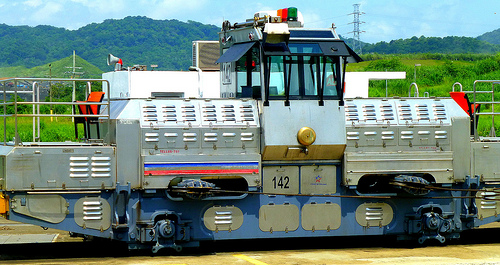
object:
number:
[271, 175, 290, 189]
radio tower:
[345, 2, 367, 55]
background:
[0, 0, 500, 72]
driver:
[212, 12, 366, 108]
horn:
[106, 52, 123, 71]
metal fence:
[0, 77, 111, 144]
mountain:
[0, 12, 222, 71]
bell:
[296, 126, 317, 146]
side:
[137, 119, 472, 189]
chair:
[449, 91, 481, 128]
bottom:
[4, 186, 500, 255]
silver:
[0, 96, 500, 190]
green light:
[286, 6, 298, 21]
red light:
[281, 8, 288, 23]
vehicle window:
[262, 165, 301, 195]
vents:
[214, 220, 233, 225]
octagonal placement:
[203, 206, 245, 231]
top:
[213, 6, 367, 71]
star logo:
[315, 175, 323, 183]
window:
[234, 42, 263, 99]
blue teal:
[214, 41, 258, 63]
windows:
[288, 43, 325, 54]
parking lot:
[1, 74, 49, 103]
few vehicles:
[1, 80, 32, 91]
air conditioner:
[191, 40, 221, 71]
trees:
[475, 33, 485, 52]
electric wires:
[302, 13, 354, 25]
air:
[303, 0, 500, 52]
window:
[266, 55, 340, 100]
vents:
[364, 131, 378, 136]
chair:
[72, 91, 106, 140]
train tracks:
[89, 232, 467, 258]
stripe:
[143, 169, 259, 176]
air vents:
[142, 99, 260, 150]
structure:
[0, 79, 500, 255]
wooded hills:
[0, 12, 496, 75]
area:
[0, 0, 500, 265]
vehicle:
[0, 6, 500, 254]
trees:
[389, 41, 393, 52]